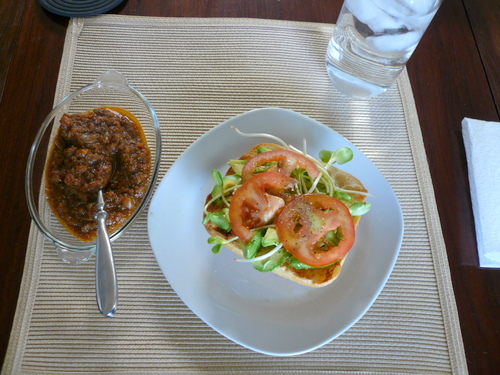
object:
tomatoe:
[276, 194, 355, 268]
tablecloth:
[0, 11, 467, 374]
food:
[201, 125, 373, 290]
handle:
[92, 189, 119, 316]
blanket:
[457, 116, 499, 271]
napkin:
[457, 116, 500, 269]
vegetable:
[201, 124, 377, 274]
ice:
[366, 31, 423, 53]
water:
[321, 0, 443, 105]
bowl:
[144, 106, 407, 360]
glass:
[323, 0, 445, 102]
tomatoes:
[278, 193, 355, 270]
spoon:
[92, 189, 119, 316]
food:
[41, 105, 153, 244]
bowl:
[21, 68, 164, 266]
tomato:
[229, 171, 300, 243]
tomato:
[239, 147, 318, 183]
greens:
[234, 242, 281, 274]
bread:
[202, 141, 368, 288]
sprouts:
[289, 144, 335, 197]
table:
[0, 0, 500, 375]